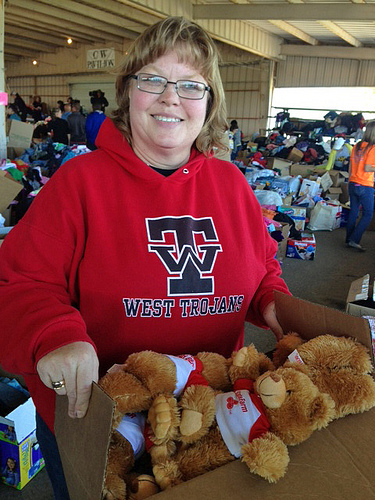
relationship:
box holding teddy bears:
[52, 287, 374, 499] [105, 330, 374, 498]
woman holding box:
[0, 17, 290, 499] [52, 287, 374, 499]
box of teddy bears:
[52, 287, 374, 499] [105, 330, 374, 498]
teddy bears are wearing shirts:
[105, 330, 374, 498] [116, 352, 271, 460]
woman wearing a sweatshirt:
[0, 17, 290, 499] [0, 114, 292, 436]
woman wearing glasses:
[0, 17, 290, 499] [129, 71, 212, 101]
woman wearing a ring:
[0, 17, 290, 499] [49, 380, 66, 390]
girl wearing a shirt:
[345, 120, 374, 253] [347, 140, 374, 185]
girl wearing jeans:
[345, 120, 374, 253] [346, 180, 374, 243]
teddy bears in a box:
[105, 330, 374, 498] [52, 287, 374, 499]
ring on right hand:
[49, 380, 66, 390] [37, 341, 99, 417]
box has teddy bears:
[52, 287, 374, 499] [105, 330, 374, 498]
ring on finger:
[49, 380, 66, 390] [50, 374, 67, 394]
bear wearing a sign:
[148, 347, 339, 487] [84, 46, 114, 69]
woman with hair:
[0, 17, 290, 499] [111, 14, 234, 157]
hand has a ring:
[37, 341, 99, 417] [49, 380, 66, 390]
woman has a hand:
[0, 17, 290, 499] [37, 341, 99, 417]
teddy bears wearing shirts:
[105, 330, 374, 498] [116, 352, 271, 460]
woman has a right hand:
[0, 17, 290, 499] [37, 341, 99, 417]